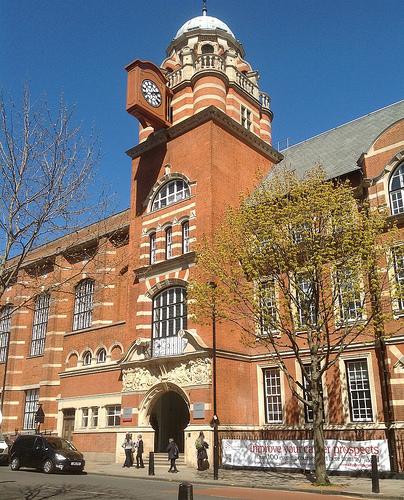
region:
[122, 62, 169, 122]
There is a clock on the building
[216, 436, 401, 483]
There is a white and red sign out front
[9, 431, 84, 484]
There is a black car parked by the curb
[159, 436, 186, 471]
A person is dressed all in black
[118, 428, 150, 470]
Two people are standing and talking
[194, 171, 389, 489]
There is a tree in front of the building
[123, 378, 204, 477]
The doorway to the building is arched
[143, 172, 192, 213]
There is a half circle window at the top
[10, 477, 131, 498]
There is a shadow of tree branches on the street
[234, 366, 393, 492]
There is a shadow of a tree on the building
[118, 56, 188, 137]
clock mounted to side of a building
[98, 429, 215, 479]
people in front of a building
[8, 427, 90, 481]
minivan parked on the street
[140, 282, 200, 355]
window of a building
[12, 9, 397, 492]
building along side of street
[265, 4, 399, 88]
blue sky in the distance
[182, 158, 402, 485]
green tree in front of building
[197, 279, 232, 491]
street lamp on a pole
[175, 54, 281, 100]
balcony on top of a building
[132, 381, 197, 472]
doorway and stairs to a building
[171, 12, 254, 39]
silver dome atop tower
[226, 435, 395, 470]
banner on side of building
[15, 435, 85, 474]
black van parked on street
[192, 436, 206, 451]
backpack on person standing on right of entrance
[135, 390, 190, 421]
archway over building entrance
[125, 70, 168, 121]
clock on front of building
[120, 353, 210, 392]
carved figures over front entrance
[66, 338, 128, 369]
arches over windows on left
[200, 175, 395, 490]
large tree to right of entrance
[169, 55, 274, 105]
balconies around top of tower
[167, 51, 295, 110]
a balcony around a tower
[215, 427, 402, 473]
a wrought iron fence in front of a building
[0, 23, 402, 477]
a large red brick building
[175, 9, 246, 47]
a dome on top of a building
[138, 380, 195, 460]
an arched entry into a building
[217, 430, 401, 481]
a banner on a fence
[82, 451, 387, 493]
a sidewalk in front of a building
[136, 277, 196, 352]
a large arched window in a building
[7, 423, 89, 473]
a black van on a road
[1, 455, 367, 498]
a road in front of a building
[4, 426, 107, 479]
Black van by a building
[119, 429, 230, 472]
People standing outside a building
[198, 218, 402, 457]
Tree by a building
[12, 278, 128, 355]
Windows on a building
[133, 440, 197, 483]
Stairs outside a building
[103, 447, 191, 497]
Gray sidewalk by a building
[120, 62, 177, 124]
Clock on a building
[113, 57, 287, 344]
Brown and white building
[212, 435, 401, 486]
Red and white sign on a building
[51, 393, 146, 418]
Tan paint on a building